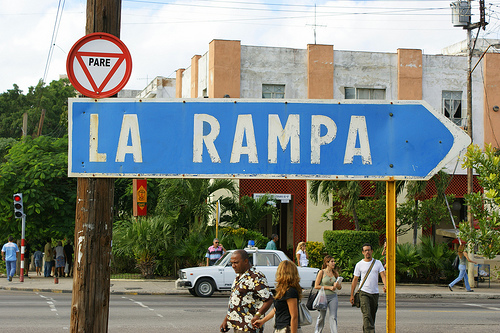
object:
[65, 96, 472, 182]
sign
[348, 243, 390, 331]
person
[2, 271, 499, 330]
street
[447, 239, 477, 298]
woman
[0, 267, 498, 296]
sidewalk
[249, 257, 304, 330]
woman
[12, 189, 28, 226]
stoplight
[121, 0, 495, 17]
powerline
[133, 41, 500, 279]
building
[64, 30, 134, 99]
sign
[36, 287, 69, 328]
line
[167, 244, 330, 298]
car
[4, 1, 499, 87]
sky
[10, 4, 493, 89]
cloud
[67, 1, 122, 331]
pole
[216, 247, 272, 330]
man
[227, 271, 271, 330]
shirt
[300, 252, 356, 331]
woman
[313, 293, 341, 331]
jeans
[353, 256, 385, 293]
shirt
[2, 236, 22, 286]
man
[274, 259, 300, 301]
hair